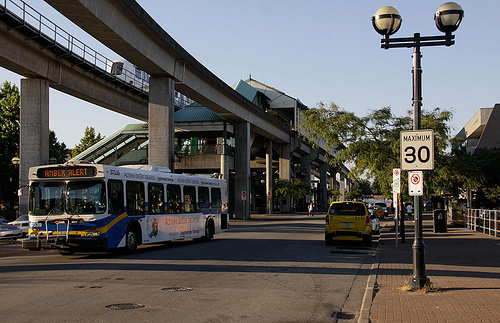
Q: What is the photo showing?
A: It is showing a road.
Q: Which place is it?
A: It is a road.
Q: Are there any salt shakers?
A: No, there are no salt shakers.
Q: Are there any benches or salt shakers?
A: No, there are no salt shakers or benches.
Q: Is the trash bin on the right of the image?
A: Yes, the trash bin is on the right of the image.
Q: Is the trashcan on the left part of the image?
A: No, the trashcan is on the right of the image.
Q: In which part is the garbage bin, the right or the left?
A: The garbage bin is on the right of the image.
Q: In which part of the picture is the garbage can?
A: The garbage can is on the right of the image.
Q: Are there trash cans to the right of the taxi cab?
A: Yes, there is a trash can to the right of the taxi cab.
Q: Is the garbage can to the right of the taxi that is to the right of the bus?
A: Yes, the garbage can is to the right of the taxi.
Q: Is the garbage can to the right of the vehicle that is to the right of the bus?
A: Yes, the garbage can is to the right of the taxi.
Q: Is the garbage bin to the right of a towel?
A: No, the garbage bin is to the right of the taxi.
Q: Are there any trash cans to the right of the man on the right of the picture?
A: Yes, there is a trash can to the right of the man.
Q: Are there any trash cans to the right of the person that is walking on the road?
A: Yes, there is a trash can to the right of the man.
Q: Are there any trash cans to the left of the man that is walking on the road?
A: No, the trash can is to the right of the man.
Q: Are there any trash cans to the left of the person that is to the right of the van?
A: No, the trash can is to the right of the man.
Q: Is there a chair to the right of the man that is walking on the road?
A: No, there is a trash can to the right of the man.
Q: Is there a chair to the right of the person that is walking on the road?
A: No, there is a trash can to the right of the man.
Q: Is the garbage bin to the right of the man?
A: Yes, the garbage bin is to the right of the man.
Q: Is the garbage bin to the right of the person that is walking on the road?
A: Yes, the garbage bin is to the right of the man.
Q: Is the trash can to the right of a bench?
A: No, the trash can is to the right of the man.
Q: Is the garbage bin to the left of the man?
A: No, the garbage bin is to the right of the man.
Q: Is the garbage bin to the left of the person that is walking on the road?
A: No, the garbage bin is to the right of the man.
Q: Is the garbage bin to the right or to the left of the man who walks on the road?
A: The garbage bin is to the right of the man.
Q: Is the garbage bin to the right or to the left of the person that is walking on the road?
A: The garbage bin is to the right of the man.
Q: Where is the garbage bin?
A: The garbage bin is on the road.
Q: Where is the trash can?
A: The garbage bin is on the road.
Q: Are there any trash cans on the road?
A: Yes, there is a trash can on the road.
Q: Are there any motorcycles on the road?
A: No, there is a trash can on the road.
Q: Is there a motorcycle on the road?
A: No, there is a trash can on the road.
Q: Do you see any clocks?
A: No, there are no clocks.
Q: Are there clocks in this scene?
A: No, there are no clocks.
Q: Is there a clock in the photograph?
A: No, there are no clocks.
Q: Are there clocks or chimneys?
A: No, there are no clocks or chimneys.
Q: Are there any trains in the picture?
A: Yes, there is a train.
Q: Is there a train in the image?
A: Yes, there is a train.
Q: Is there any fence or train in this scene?
A: Yes, there is a train.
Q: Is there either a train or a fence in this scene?
A: Yes, there is a train.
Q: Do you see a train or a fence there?
A: Yes, there is a train.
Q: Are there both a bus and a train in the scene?
A: Yes, there are both a train and a bus.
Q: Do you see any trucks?
A: No, there are no trucks.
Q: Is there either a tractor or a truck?
A: No, there are no trucks or tractors.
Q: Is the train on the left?
A: Yes, the train is on the left of the image.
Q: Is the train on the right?
A: No, the train is on the left of the image.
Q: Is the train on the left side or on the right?
A: The train is on the left of the image.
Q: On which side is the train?
A: The train is on the left of the image.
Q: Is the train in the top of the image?
A: Yes, the train is in the top of the image.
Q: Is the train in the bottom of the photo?
A: No, the train is in the top of the image.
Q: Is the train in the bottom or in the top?
A: The train is in the top of the image.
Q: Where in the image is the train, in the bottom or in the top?
A: The train is in the top of the image.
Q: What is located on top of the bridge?
A: The train is on top of the bridge.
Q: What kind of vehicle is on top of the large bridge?
A: The vehicle is a train.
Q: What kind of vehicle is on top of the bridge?
A: The vehicle is a train.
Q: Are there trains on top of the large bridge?
A: Yes, there is a train on top of the bridge.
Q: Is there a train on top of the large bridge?
A: Yes, there is a train on top of the bridge.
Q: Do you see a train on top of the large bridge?
A: Yes, there is a train on top of the bridge.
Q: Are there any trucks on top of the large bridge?
A: No, there is a train on top of the bridge.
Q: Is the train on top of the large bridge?
A: Yes, the train is on top of the bridge.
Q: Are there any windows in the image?
A: Yes, there is a window.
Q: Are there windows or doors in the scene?
A: Yes, there is a window.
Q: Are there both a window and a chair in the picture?
A: No, there is a window but no chairs.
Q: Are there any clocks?
A: No, there are no clocks.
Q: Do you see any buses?
A: Yes, there is a bus.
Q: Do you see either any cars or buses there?
A: Yes, there is a bus.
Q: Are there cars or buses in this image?
A: Yes, there is a bus.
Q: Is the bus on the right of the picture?
A: No, the bus is on the left of the image.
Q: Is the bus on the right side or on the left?
A: The bus is on the left of the image.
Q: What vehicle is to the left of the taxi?
A: The vehicle is a bus.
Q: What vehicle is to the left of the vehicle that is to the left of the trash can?
A: The vehicle is a bus.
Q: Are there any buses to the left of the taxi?
A: Yes, there is a bus to the left of the taxi.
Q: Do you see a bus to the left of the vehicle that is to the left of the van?
A: Yes, there is a bus to the left of the taxi.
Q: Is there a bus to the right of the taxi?
A: No, the bus is to the left of the taxi.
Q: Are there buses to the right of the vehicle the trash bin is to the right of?
A: No, the bus is to the left of the taxi.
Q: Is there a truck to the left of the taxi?
A: No, there is a bus to the left of the taxi.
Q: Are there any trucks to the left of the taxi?
A: No, there is a bus to the left of the taxi.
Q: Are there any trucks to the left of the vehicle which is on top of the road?
A: No, there is a bus to the left of the taxi.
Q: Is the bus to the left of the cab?
A: Yes, the bus is to the left of the cab.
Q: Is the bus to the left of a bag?
A: No, the bus is to the left of the cab.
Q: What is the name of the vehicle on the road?
A: The vehicle is a bus.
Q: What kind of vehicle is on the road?
A: The vehicle is a bus.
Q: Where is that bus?
A: The bus is on the road.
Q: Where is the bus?
A: The bus is on the road.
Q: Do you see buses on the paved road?
A: Yes, there is a bus on the road.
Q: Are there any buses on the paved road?
A: Yes, there is a bus on the road.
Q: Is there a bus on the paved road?
A: Yes, there is a bus on the road.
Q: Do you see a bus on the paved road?
A: Yes, there is a bus on the road.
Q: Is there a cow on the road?
A: No, there is a bus on the road.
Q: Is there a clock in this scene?
A: No, there are no clocks.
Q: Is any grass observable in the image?
A: Yes, there is grass.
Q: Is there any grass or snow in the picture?
A: Yes, there is grass.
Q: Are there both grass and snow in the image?
A: No, there is grass but no snow.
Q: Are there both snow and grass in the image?
A: No, there is grass but no snow.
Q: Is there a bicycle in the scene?
A: No, there are no bicycles.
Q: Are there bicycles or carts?
A: No, there are no bicycles or carts.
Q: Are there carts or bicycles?
A: No, there are no bicycles or carts.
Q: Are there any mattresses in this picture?
A: No, there are no mattresses.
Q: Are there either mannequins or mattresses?
A: No, there are no mattresses or mannequins.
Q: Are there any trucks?
A: No, there are no trucks.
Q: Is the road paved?
A: Yes, the road is paved.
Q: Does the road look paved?
A: Yes, the road is paved.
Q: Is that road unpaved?
A: No, the road is paved.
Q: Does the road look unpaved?
A: No, the road is paved.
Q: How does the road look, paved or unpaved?
A: The road is paved.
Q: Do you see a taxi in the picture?
A: Yes, there is a taxi.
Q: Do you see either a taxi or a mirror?
A: Yes, there is a taxi.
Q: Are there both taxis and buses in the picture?
A: Yes, there are both a taxi and a bus.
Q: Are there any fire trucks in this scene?
A: No, there are no fire trucks.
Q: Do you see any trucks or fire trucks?
A: No, there are no fire trucks or trucks.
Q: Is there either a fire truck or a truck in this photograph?
A: No, there are no fire trucks or trucks.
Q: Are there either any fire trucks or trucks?
A: No, there are no fire trucks or trucks.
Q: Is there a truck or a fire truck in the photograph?
A: No, there are no fire trucks or trucks.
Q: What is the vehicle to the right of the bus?
A: The vehicle is a taxi.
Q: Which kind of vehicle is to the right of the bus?
A: The vehicle is a taxi.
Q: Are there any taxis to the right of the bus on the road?
A: Yes, there is a taxi to the right of the bus.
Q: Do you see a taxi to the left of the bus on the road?
A: No, the taxi is to the right of the bus.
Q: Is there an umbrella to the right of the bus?
A: No, there is a taxi to the right of the bus.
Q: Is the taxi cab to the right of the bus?
A: Yes, the taxi cab is to the right of the bus.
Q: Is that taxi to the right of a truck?
A: No, the taxi is to the right of the bus.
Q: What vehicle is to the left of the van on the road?
A: The vehicle is a taxi.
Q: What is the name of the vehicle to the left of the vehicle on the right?
A: The vehicle is a taxi.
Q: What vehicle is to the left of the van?
A: The vehicle is a taxi.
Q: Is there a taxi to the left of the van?
A: Yes, there is a taxi to the left of the van.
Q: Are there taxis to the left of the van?
A: Yes, there is a taxi to the left of the van.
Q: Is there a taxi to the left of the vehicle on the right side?
A: Yes, there is a taxi to the left of the van.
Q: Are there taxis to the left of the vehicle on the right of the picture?
A: Yes, there is a taxi to the left of the van.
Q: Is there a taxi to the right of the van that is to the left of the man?
A: No, the taxi is to the left of the van.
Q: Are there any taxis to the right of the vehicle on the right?
A: No, the taxi is to the left of the van.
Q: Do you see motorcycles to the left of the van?
A: No, there is a taxi to the left of the van.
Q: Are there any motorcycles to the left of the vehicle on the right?
A: No, there is a taxi to the left of the van.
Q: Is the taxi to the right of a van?
A: No, the taxi is to the left of a van.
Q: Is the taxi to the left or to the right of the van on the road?
A: The taxi is to the left of the van.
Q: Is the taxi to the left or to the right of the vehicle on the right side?
A: The taxi is to the left of the van.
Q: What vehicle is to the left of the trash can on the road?
A: The vehicle is a taxi.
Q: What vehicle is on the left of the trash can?
A: The vehicle is a taxi.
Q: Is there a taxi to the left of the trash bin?
A: Yes, there is a taxi to the left of the trash bin.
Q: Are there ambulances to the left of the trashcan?
A: No, there is a taxi to the left of the trashcan.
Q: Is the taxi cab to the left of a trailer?
A: No, the taxi cab is to the left of the trash bin.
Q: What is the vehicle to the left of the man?
A: The vehicle is a taxi.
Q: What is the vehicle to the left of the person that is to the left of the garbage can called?
A: The vehicle is a taxi.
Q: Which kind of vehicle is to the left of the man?
A: The vehicle is a taxi.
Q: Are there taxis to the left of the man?
A: Yes, there is a taxi to the left of the man.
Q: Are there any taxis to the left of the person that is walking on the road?
A: Yes, there is a taxi to the left of the man.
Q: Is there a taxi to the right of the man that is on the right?
A: No, the taxi is to the left of the man.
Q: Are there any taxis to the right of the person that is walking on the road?
A: No, the taxi is to the left of the man.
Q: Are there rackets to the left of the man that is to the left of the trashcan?
A: No, there is a taxi to the left of the man.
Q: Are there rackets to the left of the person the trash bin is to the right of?
A: No, there is a taxi to the left of the man.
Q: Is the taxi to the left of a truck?
A: No, the taxi is to the left of the man.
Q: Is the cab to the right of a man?
A: No, the cab is to the left of a man.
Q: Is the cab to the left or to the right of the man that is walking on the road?
A: The cab is to the left of the man.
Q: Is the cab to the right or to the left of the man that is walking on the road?
A: The cab is to the left of the man.